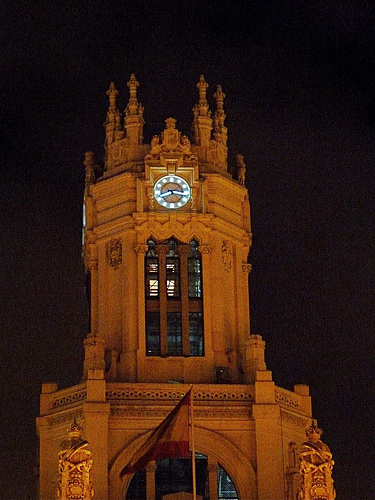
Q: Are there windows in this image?
A: Yes, there is a window.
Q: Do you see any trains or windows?
A: Yes, there is a window.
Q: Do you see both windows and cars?
A: No, there is a window but no cars.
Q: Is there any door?
A: No, there are no doors.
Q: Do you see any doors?
A: No, there are no doors.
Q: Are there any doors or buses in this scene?
A: No, there are no doors or buses.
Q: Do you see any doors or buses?
A: No, there are no doors or buses.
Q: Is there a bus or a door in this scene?
A: No, there are no doors or buses.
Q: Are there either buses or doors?
A: No, there are no doors or buses.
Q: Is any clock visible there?
A: Yes, there is a clock.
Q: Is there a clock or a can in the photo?
A: Yes, there is a clock.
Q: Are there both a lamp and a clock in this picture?
A: No, there is a clock but no lamps.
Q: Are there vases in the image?
A: No, there are no vases.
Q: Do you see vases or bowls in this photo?
A: No, there are no vases or bowls.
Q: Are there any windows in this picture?
A: Yes, there is a window.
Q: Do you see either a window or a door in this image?
A: Yes, there is a window.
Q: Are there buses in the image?
A: No, there are no buses.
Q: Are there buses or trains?
A: No, there are no buses or trains.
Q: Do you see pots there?
A: No, there are no pots.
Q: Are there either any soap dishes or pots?
A: No, there are no pots or soap dishes.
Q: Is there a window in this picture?
A: Yes, there is a window.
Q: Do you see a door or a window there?
A: Yes, there is a window.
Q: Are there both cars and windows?
A: No, there is a window but no cars.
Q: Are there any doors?
A: No, there are no doors.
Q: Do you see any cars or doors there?
A: No, there are no doors or cars.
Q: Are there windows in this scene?
A: Yes, there is a window.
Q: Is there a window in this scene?
A: Yes, there is a window.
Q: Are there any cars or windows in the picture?
A: Yes, there is a window.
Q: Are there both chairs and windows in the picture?
A: No, there is a window but no chairs.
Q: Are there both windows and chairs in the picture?
A: No, there is a window but no chairs.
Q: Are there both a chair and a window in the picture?
A: No, there is a window but no chairs.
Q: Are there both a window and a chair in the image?
A: No, there is a window but no chairs.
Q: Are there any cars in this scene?
A: No, there are no cars.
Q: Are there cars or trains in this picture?
A: No, there are no cars or trains.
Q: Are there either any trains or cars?
A: No, there are no cars or trains.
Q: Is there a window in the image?
A: Yes, there is a window.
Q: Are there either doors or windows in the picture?
A: Yes, there is a window.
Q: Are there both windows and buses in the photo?
A: No, there is a window but no buses.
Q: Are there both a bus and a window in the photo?
A: No, there is a window but no buses.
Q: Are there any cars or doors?
A: No, there are no cars or doors.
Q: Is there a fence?
A: No, there are no fences.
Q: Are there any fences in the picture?
A: No, there are no fences.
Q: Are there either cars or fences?
A: No, there are no fences or cars.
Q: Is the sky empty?
A: Yes, the sky is empty.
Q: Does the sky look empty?
A: Yes, the sky is empty.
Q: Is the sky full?
A: No, the sky is empty.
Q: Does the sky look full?
A: No, the sky is empty.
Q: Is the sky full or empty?
A: The sky is empty.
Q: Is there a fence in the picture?
A: No, there are no fences.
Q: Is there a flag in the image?
A: Yes, there is a flag.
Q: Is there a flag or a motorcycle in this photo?
A: Yes, there is a flag.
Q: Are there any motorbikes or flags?
A: Yes, there is a flag.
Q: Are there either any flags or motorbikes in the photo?
A: Yes, there is a flag.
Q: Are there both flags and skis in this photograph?
A: No, there is a flag but no skis.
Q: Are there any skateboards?
A: No, there are no skateboards.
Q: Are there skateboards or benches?
A: No, there are no skateboards or benches.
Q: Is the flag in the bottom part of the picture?
A: Yes, the flag is in the bottom of the image.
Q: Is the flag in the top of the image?
A: No, the flag is in the bottom of the image.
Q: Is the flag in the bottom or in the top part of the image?
A: The flag is in the bottom of the image.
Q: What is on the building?
A: The flag is on the building.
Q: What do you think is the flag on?
A: The flag is on the building.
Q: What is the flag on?
A: The flag is on the building.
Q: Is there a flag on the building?
A: Yes, there is a flag on the building.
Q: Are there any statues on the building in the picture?
A: No, there is a flag on the building.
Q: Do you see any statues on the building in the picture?
A: No, there is a flag on the building.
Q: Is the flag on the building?
A: Yes, the flag is on the building.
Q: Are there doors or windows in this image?
A: Yes, there is a window.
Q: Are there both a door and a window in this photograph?
A: No, there is a window but no doors.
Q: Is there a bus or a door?
A: No, there are no doors or buses.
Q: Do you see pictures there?
A: No, there are no pictures.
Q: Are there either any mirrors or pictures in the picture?
A: No, there are no pictures or mirrors.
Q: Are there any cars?
A: No, there are no cars.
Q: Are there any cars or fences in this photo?
A: No, there are no cars or fences.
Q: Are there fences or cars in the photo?
A: No, there are no cars or fences.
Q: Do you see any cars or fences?
A: No, there are no cars or fences.